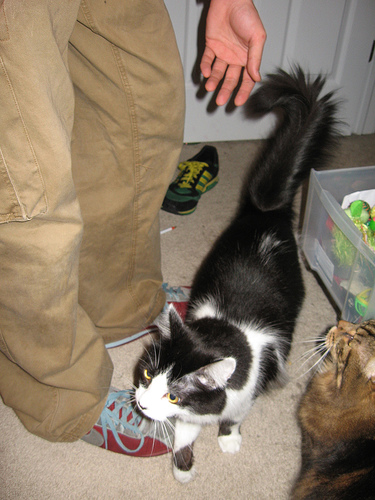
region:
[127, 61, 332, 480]
a black and white cat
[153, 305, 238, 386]
the ears of a cat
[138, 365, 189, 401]
eyes of a cat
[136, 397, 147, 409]
nose of a cat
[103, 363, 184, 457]
whiskers of a cat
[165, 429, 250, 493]
paws of a cat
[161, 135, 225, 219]
a tennis shoe on the floor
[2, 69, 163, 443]
a person wearing tan pants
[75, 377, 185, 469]
a blue and red shoe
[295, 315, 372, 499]
a brown cat looking up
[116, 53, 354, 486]
a black and white cat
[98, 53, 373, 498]
two cats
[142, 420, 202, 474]
whiskers of the cat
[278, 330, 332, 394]
whiskers of the cat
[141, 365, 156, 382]
an eye of the cat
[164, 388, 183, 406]
an eye of the cat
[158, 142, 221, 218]
a shoe in the room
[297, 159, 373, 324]
a bin full of stuff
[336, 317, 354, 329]
nose of the cat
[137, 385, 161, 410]
nose of the cat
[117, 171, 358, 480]
a cat that is inside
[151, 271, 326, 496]
a black and whtie cat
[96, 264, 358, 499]
a cat that is walking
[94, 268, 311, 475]
black and white cat walking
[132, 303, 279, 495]
an inside cat walking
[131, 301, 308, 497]
a black and white cat inside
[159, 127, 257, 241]
a green and black shoe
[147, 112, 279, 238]
a shoe with yellow shoe strings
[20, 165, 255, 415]
a person wearing pants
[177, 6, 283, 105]
hand of the person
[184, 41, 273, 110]
fingers on the person's hand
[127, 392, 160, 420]
nose of the cat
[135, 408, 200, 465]
whiskers on the cat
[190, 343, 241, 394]
ear of the cat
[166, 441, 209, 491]
paw of the cat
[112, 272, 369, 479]
two cats in the photo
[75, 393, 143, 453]
laces on the shoe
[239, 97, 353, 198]
tail of the cat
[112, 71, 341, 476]
black and white cat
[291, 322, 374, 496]
brown cat on the right side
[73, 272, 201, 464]
red and gray shoes with blue laces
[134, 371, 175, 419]
white markings on cat's face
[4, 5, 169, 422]
cargo pants man is wearing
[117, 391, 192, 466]
whiskers on the black and white cat's face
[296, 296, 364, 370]
whiskers on brown cat's face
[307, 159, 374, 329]
plastic drawer next to cats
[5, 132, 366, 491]
beige carpeting in the room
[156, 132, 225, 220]
black, yellow, and green shoe